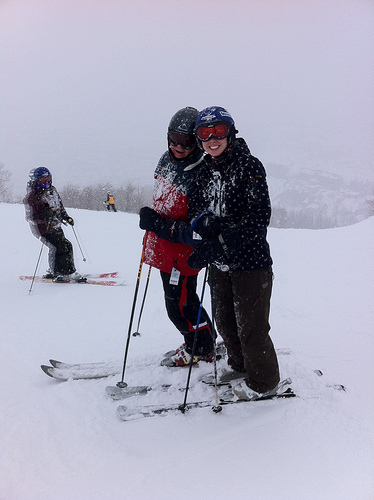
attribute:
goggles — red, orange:
[177, 121, 262, 155]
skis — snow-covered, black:
[34, 358, 307, 431]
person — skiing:
[21, 163, 82, 286]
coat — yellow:
[92, 197, 131, 209]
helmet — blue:
[177, 92, 235, 146]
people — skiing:
[12, 108, 288, 394]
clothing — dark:
[212, 154, 278, 385]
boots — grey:
[213, 376, 296, 402]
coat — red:
[148, 151, 212, 271]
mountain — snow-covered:
[253, 133, 370, 221]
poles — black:
[177, 250, 234, 419]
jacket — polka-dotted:
[180, 145, 260, 278]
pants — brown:
[194, 246, 296, 377]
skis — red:
[32, 256, 129, 308]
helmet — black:
[161, 107, 219, 168]